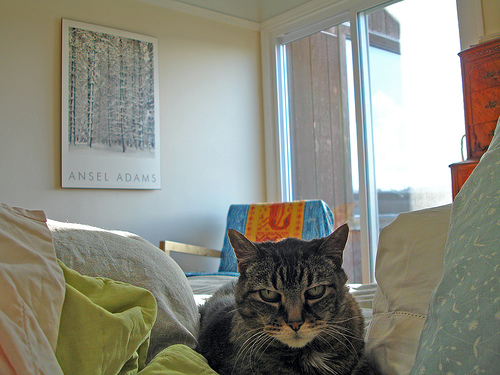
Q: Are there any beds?
A: Yes, there is a bed.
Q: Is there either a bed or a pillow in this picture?
A: Yes, there is a bed.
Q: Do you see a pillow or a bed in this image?
A: Yes, there is a bed.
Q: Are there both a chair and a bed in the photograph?
A: Yes, there are both a bed and a chair.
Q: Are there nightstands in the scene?
A: No, there are no nightstands.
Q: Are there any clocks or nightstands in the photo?
A: No, there are no nightstands or clocks.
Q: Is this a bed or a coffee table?
A: This is a bed.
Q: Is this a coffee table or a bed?
A: This is a bed.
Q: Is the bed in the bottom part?
A: Yes, the bed is in the bottom of the image.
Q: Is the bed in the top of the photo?
A: No, the bed is in the bottom of the image.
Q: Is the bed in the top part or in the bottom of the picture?
A: The bed is in the bottom of the image.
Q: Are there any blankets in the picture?
A: Yes, there is a blanket.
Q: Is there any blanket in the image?
A: Yes, there is a blanket.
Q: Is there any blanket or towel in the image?
A: Yes, there is a blanket.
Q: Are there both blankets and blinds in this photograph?
A: No, there is a blanket but no blinds.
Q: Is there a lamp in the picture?
A: No, there are no lamps.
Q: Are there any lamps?
A: No, there are no lamps.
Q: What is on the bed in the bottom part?
A: The blanket is on the bed.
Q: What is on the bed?
A: The blanket is on the bed.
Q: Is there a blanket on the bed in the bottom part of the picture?
A: Yes, there is a blanket on the bed.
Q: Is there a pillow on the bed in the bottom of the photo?
A: No, there is a blanket on the bed.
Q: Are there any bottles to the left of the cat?
A: No, there is a blanket to the left of the cat.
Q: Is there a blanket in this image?
A: Yes, there is a blanket.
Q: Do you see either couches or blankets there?
A: Yes, there is a blanket.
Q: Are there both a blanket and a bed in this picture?
A: Yes, there are both a blanket and a bed.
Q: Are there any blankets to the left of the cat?
A: Yes, there is a blanket to the left of the cat.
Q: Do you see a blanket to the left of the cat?
A: Yes, there is a blanket to the left of the cat.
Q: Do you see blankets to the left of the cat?
A: Yes, there is a blanket to the left of the cat.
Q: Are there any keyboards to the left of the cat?
A: No, there is a blanket to the left of the cat.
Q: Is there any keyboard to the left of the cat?
A: No, there is a blanket to the left of the cat.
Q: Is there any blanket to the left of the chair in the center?
A: Yes, there is a blanket to the left of the chair.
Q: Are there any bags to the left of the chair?
A: No, there is a blanket to the left of the chair.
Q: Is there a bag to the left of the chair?
A: No, there is a blanket to the left of the chair.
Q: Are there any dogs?
A: No, there are no dogs.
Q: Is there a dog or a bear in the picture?
A: No, there are no dogs or bears.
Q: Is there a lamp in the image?
A: No, there are no lamps.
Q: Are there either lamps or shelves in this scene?
A: No, there are no lamps or shelves.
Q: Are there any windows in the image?
A: Yes, there is a window.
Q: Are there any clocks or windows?
A: Yes, there is a window.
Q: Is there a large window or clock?
A: Yes, there is a large window.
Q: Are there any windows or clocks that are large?
A: Yes, the window is large.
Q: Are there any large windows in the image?
A: Yes, there is a large window.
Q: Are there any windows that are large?
A: Yes, there is a window that is large.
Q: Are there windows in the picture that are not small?
A: Yes, there is a large window.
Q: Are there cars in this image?
A: No, there are no cars.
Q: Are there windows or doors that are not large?
A: No, there is a window but it is large.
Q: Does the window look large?
A: Yes, the window is large.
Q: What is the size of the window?
A: The window is large.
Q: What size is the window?
A: The window is large.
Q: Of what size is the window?
A: The window is large.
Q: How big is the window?
A: The window is large.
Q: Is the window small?
A: No, the window is large.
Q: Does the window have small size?
A: No, the window is large.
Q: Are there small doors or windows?
A: No, there is a window but it is large.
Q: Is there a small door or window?
A: No, there is a window but it is large.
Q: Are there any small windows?
A: No, there is a window but it is large.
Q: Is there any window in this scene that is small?
A: No, there is a window but it is large.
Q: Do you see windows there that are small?
A: No, there is a window but it is large.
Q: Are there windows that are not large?
A: No, there is a window but it is large.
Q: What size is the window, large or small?
A: The window is large.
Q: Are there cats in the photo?
A: Yes, there is a cat.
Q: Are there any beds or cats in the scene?
A: Yes, there is a cat.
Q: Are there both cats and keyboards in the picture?
A: No, there is a cat but no keyboards.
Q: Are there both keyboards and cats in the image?
A: No, there is a cat but no keyboards.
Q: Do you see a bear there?
A: No, there are no bears.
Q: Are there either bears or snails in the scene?
A: No, there are no bears or snails.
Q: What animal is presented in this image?
A: The animal is a cat.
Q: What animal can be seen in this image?
A: The animal is a cat.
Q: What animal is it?
A: The animal is a cat.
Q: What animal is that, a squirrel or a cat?
A: This is a cat.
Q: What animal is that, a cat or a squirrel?
A: This is a cat.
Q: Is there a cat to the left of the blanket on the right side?
A: Yes, there is a cat to the left of the blanket.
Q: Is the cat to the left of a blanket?
A: Yes, the cat is to the left of a blanket.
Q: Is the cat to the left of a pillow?
A: No, the cat is to the left of a blanket.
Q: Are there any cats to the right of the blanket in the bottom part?
A: Yes, there is a cat to the right of the blanket.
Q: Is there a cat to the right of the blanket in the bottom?
A: Yes, there is a cat to the right of the blanket.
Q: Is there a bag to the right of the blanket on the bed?
A: No, there is a cat to the right of the blanket.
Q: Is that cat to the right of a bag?
A: No, the cat is to the right of the blanket.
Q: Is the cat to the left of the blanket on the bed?
A: No, the cat is to the right of the blanket.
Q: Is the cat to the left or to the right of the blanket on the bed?
A: The cat is to the right of the blanket.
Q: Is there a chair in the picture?
A: Yes, there is a chair.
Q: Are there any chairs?
A: Yes, there is a chair.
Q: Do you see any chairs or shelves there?
A: Yes, there is a chair.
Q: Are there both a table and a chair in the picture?
A: No, there is a chair but no tables.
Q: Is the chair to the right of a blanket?
A: Yes, the chair is to the right of a blanket.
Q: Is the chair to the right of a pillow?
A: No, the chair is to the right of a blanket.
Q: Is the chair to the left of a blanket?
A: No, the chair is to the right of a blanket.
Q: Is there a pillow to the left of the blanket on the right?
A: No, there is a chair to the left of the blanket.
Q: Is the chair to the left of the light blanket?
A: Yes, the chair is to the left of the blanket.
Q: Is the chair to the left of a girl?
A: No, the chair is to the left of the blanket.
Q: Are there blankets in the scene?
A: Yes, there is a blanket.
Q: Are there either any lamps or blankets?
A: Yes, there is a blanket.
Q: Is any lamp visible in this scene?
A: No, there are no lamps.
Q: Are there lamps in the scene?
A: No, there are no lamps.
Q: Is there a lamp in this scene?
A: No, there are no lamps.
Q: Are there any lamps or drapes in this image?
A: No, there are no lamps or drapes.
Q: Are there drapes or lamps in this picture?
A: No, there are no lamps or drapes.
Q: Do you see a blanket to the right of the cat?
A: Yes, there is a blanket to the right of the cat.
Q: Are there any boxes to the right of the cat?
A: No, there is a blanket to the right of the cat.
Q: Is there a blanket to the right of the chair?
A: Yes, there is a blanket to the right of the chair.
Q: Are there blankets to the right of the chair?
A: Yes, there is a blanket to the right of the chair.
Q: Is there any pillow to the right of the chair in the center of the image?
A: No, there is a blanket to the right of the chair.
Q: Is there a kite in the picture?
A: No, there are no kites.